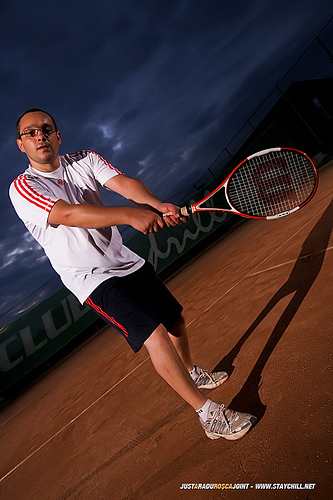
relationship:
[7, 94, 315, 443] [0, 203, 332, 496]
man above tennis court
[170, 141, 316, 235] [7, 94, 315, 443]
racket with man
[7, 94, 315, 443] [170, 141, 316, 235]
man with racket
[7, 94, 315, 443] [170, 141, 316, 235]
man has racket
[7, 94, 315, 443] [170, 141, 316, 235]
man using racket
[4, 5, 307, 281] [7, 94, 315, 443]
sky above man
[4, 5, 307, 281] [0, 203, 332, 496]
sky above tennis court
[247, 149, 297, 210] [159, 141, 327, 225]
logo on racket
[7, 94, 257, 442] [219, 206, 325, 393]
man has shadow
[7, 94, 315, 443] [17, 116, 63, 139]
man wears eyeglasses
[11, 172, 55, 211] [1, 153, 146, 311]
stripes on shirt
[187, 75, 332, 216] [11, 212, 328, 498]
fence around tennis court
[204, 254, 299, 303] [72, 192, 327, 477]
stripe on tennis court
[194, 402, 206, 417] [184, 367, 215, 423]
lines on socks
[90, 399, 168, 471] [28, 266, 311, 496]
marks in court